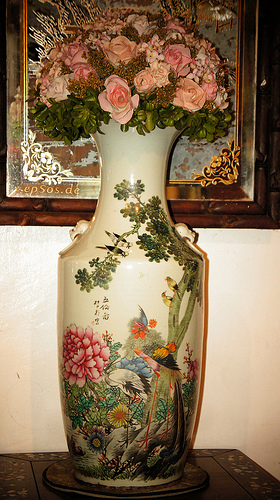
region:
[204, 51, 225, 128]
the flowers are pink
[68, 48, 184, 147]
the flowers are pink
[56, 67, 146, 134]
the flowers are pink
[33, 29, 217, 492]
flowers in the giant vase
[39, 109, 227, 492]
a tall painted vase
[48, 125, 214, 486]
a tall painted vase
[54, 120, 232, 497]
a tall painted vase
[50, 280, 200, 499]
a painting of flowers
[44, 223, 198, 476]
a painting of flowers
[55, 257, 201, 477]
a painting of flowers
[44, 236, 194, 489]
a painting of flowers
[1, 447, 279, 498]
a decorative wooden table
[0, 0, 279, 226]
a framed picture on a wall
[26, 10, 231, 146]
a pink and green bouquet in a vase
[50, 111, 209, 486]
a large painted vase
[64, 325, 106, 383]
a large pink flower on a vase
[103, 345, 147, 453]
a white and black long legged bird on a vase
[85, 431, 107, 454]
a blue and yellow flower on a vase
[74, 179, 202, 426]
a green tree on a vase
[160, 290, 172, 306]
a yellow bird on a vase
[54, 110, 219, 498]
a large flower vase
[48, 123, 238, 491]
a painted flower vase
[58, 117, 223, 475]
the vase has artwork on it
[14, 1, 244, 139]
a bouquet of flowers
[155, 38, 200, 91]
this is a pink rose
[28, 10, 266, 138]
a bouquet of roses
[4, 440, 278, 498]
the table is black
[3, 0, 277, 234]
there is a wooden frame on the wall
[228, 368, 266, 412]
part of the wall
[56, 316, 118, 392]
a pink flower painted on the vase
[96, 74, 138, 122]
A pink flower in a vase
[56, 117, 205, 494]
A vase with flowers painted on it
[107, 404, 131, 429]
A yellow flower on a vase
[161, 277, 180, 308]
Birds painted on a vase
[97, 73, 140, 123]
the very light pink rose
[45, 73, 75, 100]
the very light pink rose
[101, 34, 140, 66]
the very light pink rose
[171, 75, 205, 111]
the very light pink rose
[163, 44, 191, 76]
the very light pink rose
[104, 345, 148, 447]
the painting of the bird on the vase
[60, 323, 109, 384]
the large pink flower painting on the vace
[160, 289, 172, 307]
the yellow and blue painting of a bird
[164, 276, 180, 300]
the yellow and blue painting of a bird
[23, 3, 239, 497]
vase full of flowers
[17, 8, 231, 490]
ceramic flower vase with paintings on the side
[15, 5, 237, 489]
A decorative ceramic flower vase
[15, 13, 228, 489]
A decorative ceramic vase full of flowers with colorful art on the outside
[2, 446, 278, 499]
A brown wooden table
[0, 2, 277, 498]
A vase on a table